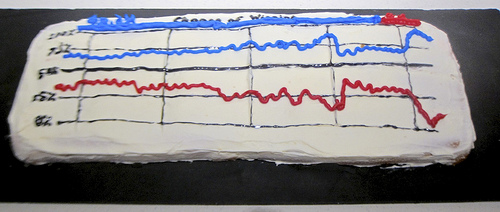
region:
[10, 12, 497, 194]
a long cake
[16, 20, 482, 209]
a long cake on a table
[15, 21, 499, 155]
a long sheet cake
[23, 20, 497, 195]
a cake with a graph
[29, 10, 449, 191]
a graph on a cake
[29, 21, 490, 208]
a long graph cake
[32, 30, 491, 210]
a graph cake on the table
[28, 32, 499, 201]
a graph cake with white frosting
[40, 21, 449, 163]
graph cake with wiggle lines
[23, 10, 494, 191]
a graph cake with red and blue lines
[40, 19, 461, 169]
Design on a cake.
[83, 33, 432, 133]
Lines on the cake.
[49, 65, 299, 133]
Red line on the cake.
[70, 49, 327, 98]
Black line on the cake.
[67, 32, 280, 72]
Blue line on the cake.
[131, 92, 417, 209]
icing on the cake.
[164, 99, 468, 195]
White frosting on the cake.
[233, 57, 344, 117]
Red line of icing.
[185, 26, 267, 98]
Blue and black line of icing.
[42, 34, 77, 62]
number in icing on the cake.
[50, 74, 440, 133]
the stripe is red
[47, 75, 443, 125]
the stripe is curvy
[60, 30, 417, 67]
the stripe is curvy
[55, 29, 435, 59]
the stripe is blue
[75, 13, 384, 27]
the stripe is flat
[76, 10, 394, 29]
the stripe is blue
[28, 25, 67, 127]
the numbers are black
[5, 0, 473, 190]
the cake is rectangular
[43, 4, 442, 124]
the cake looks like a chart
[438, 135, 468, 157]
the icing is missing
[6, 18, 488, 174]
a cake made to look like a cardiogram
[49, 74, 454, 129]
a red squiggle frosting line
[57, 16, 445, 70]
two jagged blue lines of frosting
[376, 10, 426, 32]
a section of red frosting at the end of blue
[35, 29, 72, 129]
black frosting numbers on a cake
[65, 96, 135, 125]
black lines of frosting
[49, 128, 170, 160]
white frosting on a cake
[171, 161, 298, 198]
the dark wood of a table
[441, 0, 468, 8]
the white wall behind a cake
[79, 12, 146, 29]
blue numbers written in frosting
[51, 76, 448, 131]
line of frosting on a cake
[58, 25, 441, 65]
line of frosting on a cake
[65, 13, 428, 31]
line of frosting on a cake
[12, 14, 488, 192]
cake with frosting on top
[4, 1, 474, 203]
cake with white frosting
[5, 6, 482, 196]
cake looking like a bar graph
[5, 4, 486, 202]
large cake with frosting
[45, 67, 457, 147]
red line of frosting on a cake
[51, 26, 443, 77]
blue line of frosting on a cake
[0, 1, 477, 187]
cake with white red and blue frosting